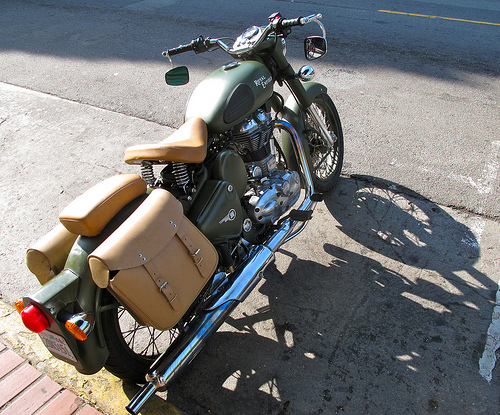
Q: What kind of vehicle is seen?
A: Motorcycle.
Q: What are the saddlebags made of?
A: Leather.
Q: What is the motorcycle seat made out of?
A: Beige leather.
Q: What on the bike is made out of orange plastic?
A: Turn signals.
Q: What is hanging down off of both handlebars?
A: Mirrors.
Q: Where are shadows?
A: On the ground.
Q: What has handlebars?
A: The motorcycle.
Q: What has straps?
A: A brown bag.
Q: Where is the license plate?
A: On back of the motorcycle.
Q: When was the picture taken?
A: During the daytime.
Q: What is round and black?
A: Tires.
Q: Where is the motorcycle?
A: On side of a road.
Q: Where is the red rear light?
A: Above the license plate.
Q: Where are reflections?
A: In the side mirrors.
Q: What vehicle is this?
A: Motorcycle.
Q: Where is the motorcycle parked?
A: Parking lot.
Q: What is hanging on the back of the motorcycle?
A: Bag.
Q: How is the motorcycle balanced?
A: Kickstand.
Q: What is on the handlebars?
A: Side mirrors.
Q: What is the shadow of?
A: The motorcycle.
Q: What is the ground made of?
A: Gravel.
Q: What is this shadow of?
A: Front tire.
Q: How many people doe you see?
A: None.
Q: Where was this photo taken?
A: Outside on the street.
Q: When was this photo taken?
A: During the day.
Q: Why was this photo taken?
A: To show off the bike.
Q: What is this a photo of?
A: A motorcycle.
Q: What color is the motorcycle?
A: Army green.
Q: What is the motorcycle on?
A: The street.